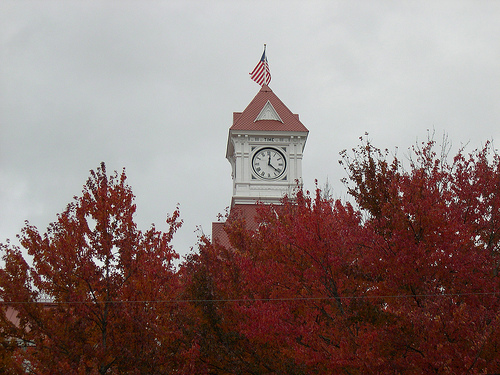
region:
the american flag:
[245, 36, 273, 84]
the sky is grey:
[3, 2, 496, 250]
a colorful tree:
[38, 178, 174, 369]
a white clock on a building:
[251, 138, 288, 178]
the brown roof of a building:
[228, 84, 304, 137]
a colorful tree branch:
[278, 228, 328, 271]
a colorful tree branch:
[378, 232, 411, 277]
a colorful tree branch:
[274, 312, 340, 362]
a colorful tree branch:
[438, 293, 474, 353]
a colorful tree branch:
[122, 265, 185, 329]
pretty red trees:
[0, 118, 497, 370]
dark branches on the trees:
[0, 148, 497, 370]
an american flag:
[244, 40, 275, 94]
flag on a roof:
[234, 38, 282, 99]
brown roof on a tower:
[214, 78, 329, 153]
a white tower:
[204, 28, 325, 219]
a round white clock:
[247, 142, 297, 186]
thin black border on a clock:
[248, 135, 296, 193]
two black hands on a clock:
[261, 150, 301, 187]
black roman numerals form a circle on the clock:
[241, 145, 301, 187]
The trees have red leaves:
[34, 159, 490, 369]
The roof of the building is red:
[197, 54, 353, 225]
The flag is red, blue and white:
[237, 39, 284, 97]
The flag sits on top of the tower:
[219, 41, 315, 158]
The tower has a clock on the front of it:
[222, 120, 319, 230]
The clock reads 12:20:
[218, 125, 315, 211]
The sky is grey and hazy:
[71, 43, 448, 203]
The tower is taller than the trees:
[196, 37, 368, 312]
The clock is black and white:
[201, 92, 313, 198]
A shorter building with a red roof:
[6, 276, 112, 368]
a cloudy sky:
[159, 14, 446, 346]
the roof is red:
[185, 58, 391, 277]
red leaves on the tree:
[32, 132, 215, 350]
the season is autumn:
[15, 122, 234, 370]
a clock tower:
[240, 137, 320, 204]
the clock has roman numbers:
[223, 110, 328, 213]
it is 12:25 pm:
[203, 60, 335, 220]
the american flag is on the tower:
[198, 37, 393, 232]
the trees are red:
[213, 70, 405, 323]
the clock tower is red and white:
[193, 74, 458, 369]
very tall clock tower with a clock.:
[184, 69, 325, 250]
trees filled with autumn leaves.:
[251, 239, 405, 319]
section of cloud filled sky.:
[96, 99, 196, 151]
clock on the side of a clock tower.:
[232, 133, 301, 215]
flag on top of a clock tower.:
[246, 23, 287, 93]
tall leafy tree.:
[49, 154, 198, 373]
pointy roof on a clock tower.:
[219, 76, 321, 147]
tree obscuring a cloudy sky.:
[329, 124, 422, 222]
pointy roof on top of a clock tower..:
[237, 89, 302, 131]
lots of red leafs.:
[196, 221, 329, 361]